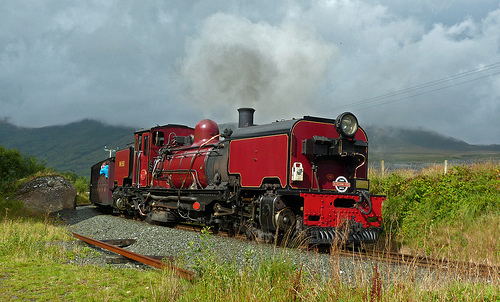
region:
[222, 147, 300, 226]
side of a train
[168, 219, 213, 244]
edge of a rail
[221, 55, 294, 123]
part of a smoke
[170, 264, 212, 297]
part of some grass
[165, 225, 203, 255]
part of a ground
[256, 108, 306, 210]
edge of a train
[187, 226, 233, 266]
part of a ground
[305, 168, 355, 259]
part of a train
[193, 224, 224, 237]
edge of a rail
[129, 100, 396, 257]
A red and black train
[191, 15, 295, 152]
Steam coming from a train engine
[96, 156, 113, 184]
A man wearing a blue shirt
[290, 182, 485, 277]
A train on train tracks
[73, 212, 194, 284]
Gravel between railroad tracks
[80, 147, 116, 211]
A train car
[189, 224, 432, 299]
Weeds growing next to a train track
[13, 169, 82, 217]
A big gray rock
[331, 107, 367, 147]
The light on the front of a train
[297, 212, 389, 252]
A bumper of a steam engine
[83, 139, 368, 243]
a red train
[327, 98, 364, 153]
a large single headlight on a train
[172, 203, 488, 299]
tall grass and weeds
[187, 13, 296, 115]
black smoke coming out of a train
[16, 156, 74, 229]
a large grey boulder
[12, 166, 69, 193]
lichens growing on a rock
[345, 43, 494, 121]
a group of three wires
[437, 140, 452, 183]
a white fence post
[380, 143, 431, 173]
wet marsh land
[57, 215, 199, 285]
a spare train track rail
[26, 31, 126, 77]
this is the sky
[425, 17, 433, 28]
the sky is blue in color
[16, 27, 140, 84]
the sky has some clouds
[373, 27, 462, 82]
the clouds are white in color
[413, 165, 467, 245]
this is the grass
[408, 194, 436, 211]
the grass is green in color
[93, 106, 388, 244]
this is a train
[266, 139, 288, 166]
the train is red in color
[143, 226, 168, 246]
these are many pebbles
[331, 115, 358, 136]
this is the train headlight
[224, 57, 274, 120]
gray smoke from stack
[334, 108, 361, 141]
light on front of train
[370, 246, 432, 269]
tracks in front of train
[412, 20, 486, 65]
white clouds in sky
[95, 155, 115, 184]
person in train window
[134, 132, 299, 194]
red body of train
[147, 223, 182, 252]
gravel on side of tracks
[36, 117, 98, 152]
side of hill on horizon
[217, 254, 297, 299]
tall weeds in foreground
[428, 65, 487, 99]
black lines suspended in air